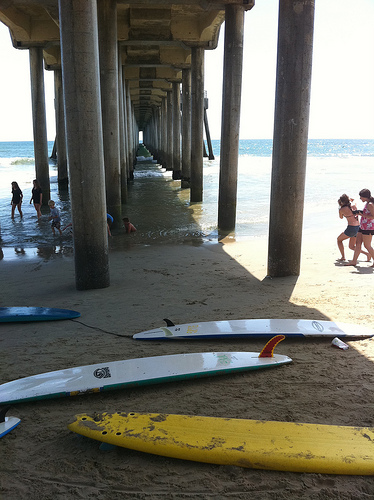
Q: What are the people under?
A: The Pier.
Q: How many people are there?
A: Seven.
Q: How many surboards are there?
A: Five.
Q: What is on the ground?
A: Surfboards.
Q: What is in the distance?
A: The Ocean.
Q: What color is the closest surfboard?
A: Yellow.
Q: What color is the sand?
A: Brown.